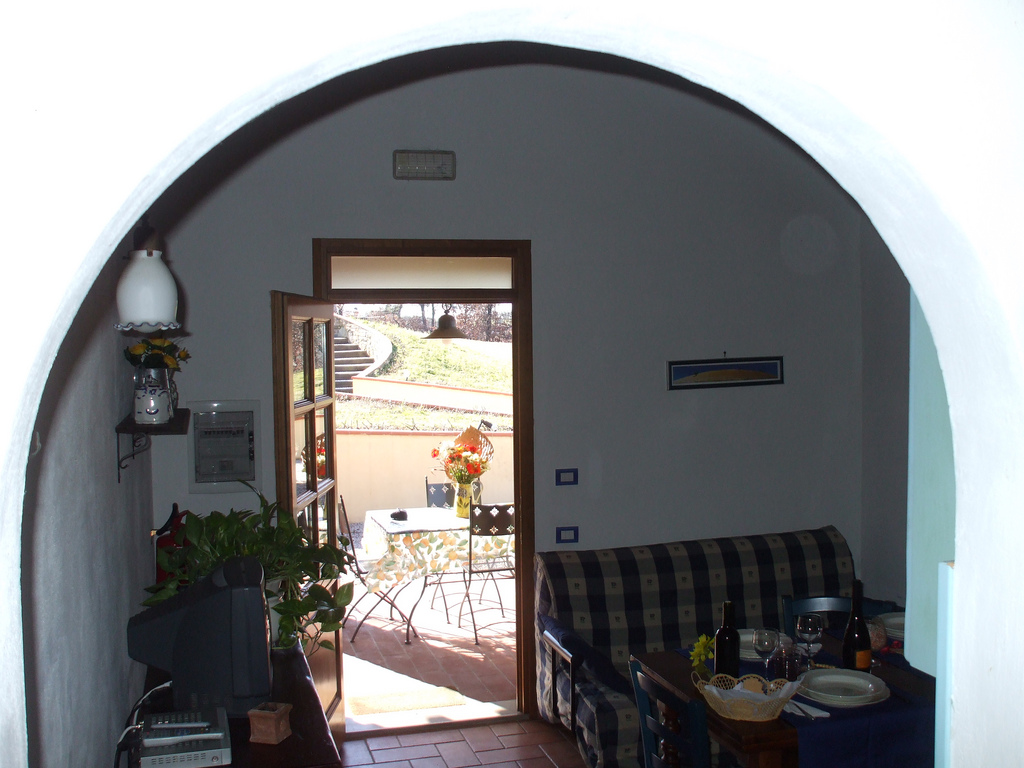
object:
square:
[640, 575, 660, 592]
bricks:
[395, 728, 465, 747]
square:
[642, 608, 660, 626]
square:
[635, 558, 656, 575]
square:
[773, 562, 791, 580]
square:
[707, 568, 726, 586]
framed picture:
[664, 356, 781, 391]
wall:
[538, 146, 785, 344]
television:
[125, 557, 274, 716]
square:
[603, 577, 624, 595]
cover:
[538, 528, 854, 661]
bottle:
[715, 600, 740, 680]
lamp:
[114, 228, 184, 334]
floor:
[112, 710, 592, 762]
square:
[622, 575, 641, 595]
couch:
[539, 524, 855, 766]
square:
[555, 595, 572, 613]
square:
[742, 583, 761, 600]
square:
[571, 610, 592, 628]